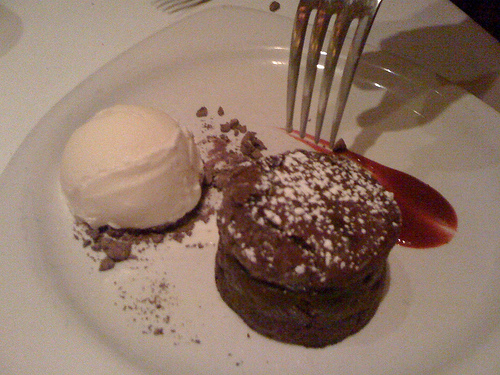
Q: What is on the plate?
A: Dessert.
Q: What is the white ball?
A: Ice cream.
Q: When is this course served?
A: Last.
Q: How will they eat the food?
A: With a fork.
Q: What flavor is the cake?
A: Chocolate.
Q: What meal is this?
A: Dessert.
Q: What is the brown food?
A: Cake.